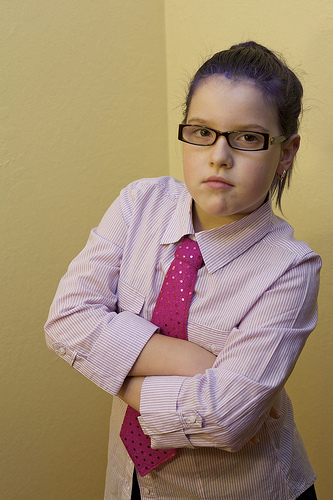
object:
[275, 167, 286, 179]
earring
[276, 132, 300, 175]
ear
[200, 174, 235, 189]
mouth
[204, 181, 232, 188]
lip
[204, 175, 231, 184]
lip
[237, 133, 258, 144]
eye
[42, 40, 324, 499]
girl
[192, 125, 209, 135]
eye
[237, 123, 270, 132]
eyebrow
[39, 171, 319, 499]
shirt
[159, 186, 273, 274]
shirt collar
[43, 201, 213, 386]
arms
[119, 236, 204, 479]
tie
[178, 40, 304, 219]
head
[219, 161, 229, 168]
nostril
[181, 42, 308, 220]
hair